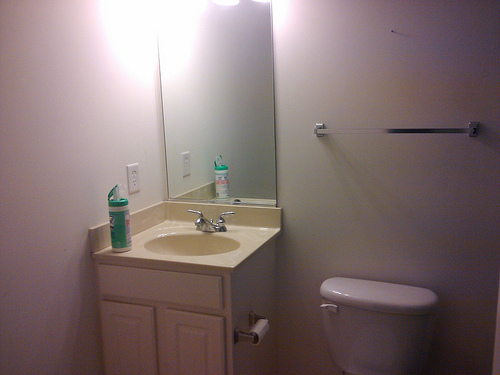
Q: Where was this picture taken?
A: A bathroom.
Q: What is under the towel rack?
A: A toilet.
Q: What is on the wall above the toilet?
A: A towel rack.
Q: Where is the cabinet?
A: On the sink.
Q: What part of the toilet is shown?
A: The water holding tank.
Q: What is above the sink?
A: The bathroom wall mirror.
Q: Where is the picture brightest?
A: The reflection of light on the mirror and wall.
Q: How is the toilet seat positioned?
A: It's down.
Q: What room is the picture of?
A: Bathroom.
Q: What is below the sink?
A: Cabinets.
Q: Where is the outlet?
A: On the wall.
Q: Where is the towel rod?
A: Above the toilet.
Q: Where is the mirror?
A: Above the sink.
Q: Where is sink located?
A: Left corner.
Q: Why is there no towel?
A: Being washed.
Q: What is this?
A: A bathroom.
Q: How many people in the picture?
A: None.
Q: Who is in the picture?
A: No one.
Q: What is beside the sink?
A: A toilet.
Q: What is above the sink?
A: A mirror.